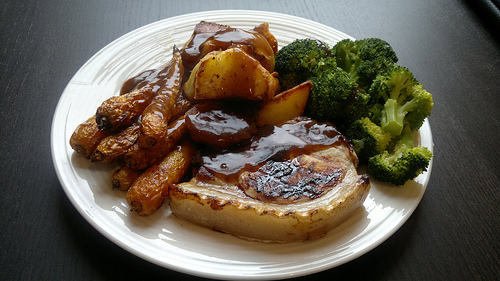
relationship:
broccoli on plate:
[274, 37, 434, 187] [49, 9, 436, 278]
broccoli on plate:
[274, 37, 434, 187] [70, 22, 441, 278]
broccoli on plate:
[274, 37, 434, 187] [162, 231, 273, 278]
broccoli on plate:
[369, 127, 431, 184] [49, 9, 436, 278]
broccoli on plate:
[376, 63, 431, 134] [49, 9, 436, 278]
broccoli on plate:
[335, 37, 394, 87] [49, 9, 436, 278]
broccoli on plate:
[312, 68, 370, 135] [49, 9, 436, 278]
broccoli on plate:
[274, 38, 332, 88] [49, 9, 436, 278]